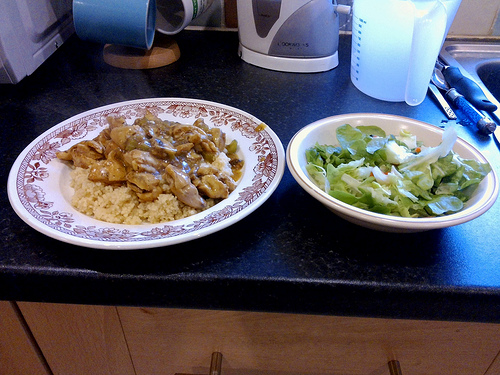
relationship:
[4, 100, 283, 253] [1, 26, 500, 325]
plate on counter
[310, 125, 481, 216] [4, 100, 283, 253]
salad on plate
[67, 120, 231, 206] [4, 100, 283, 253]
meat on plate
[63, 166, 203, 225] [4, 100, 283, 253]
rice on plate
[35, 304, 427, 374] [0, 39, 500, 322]
cabinets under counter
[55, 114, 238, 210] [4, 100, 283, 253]
meat stew on plate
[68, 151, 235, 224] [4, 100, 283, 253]
rice on plate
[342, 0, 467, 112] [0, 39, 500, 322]
cup on counter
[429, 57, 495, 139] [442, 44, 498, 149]
utensils on edge of sink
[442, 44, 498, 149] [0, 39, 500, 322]
sink on counter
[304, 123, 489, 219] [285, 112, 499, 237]
salad in white bowl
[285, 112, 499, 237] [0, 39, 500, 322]
white bowl on counter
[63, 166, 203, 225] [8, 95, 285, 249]
rice on plate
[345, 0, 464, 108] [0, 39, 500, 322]
cup on counter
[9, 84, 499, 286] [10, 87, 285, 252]
counter below dish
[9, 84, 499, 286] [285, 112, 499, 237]
counter below white bowl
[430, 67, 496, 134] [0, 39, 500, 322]
spoon on counter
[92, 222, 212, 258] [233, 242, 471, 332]
plate on counter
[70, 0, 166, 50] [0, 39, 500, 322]
cup on counter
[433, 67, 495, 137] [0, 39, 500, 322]
utensil on counter